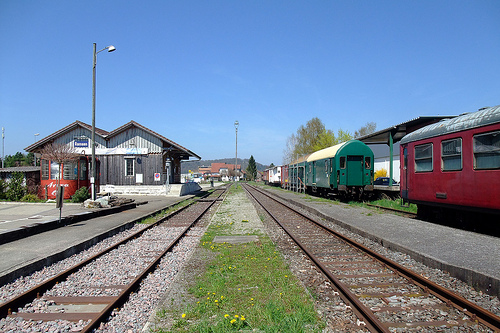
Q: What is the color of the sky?
A: Blue.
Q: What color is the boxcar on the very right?
A: Red.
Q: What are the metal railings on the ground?
A: Railroad tracks.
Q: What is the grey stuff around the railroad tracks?
A: Gravel.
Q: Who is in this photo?
A: No one.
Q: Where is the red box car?
A: On the right.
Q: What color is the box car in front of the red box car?
A: Green.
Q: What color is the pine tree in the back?
A: Green.